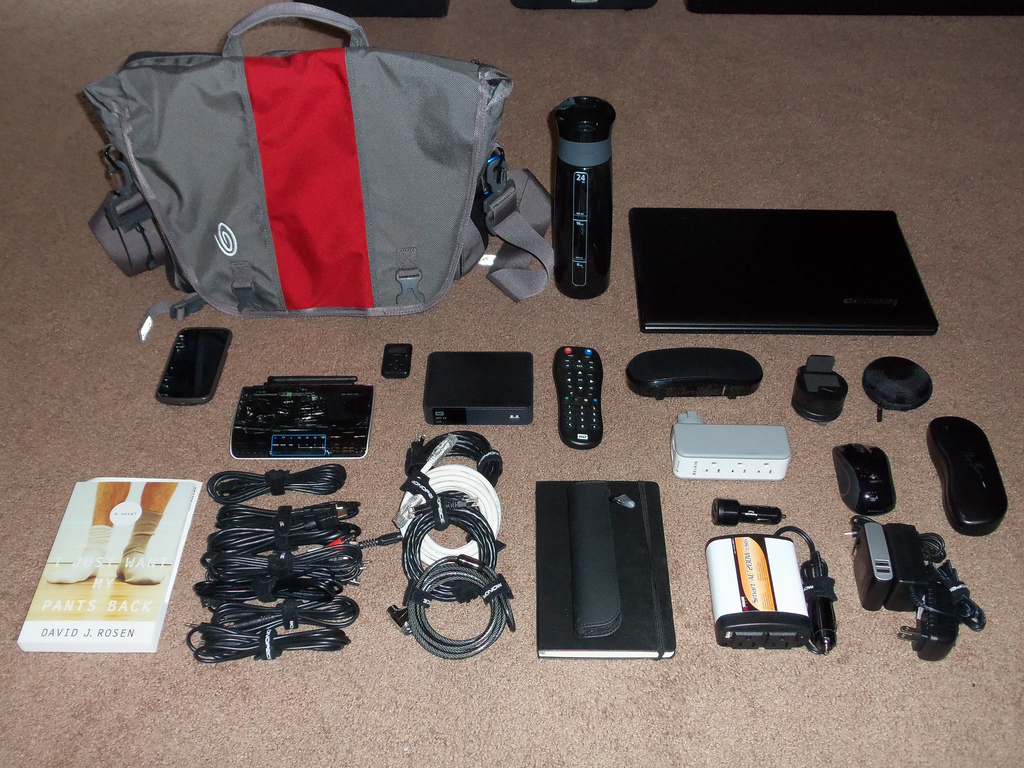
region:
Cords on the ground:
[184, 416, 524, 669]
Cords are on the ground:
[171, 419, 522, 676]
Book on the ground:
[10, 456, 219, 666]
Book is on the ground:
[13, 460, 213, 664]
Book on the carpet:
[11, 460, 214, 670]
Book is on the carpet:
[7, 457, 213, 674]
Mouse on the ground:
[823, 428, 915, 521]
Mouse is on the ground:
[820, 431, 907, 521]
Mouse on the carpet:
[822, 430, 902, 526]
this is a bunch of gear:
[96, 124, 926, 679]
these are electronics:
[64, 101, 909, 636]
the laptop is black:
[593, 177, 1008, 370]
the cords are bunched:
[204, 470, 464, 709]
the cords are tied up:
[190, 458, 397, 703]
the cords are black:
[234, 508, 371, 668]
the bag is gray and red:
[146, 78, 421, 276]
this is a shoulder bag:
[157, 69, 543, 346]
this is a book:
[58, 440, 183, 717]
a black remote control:
[550, 340, 605, 451]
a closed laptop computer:
[623, 200, 941, 336]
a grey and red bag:
[78, 1, 562, 321]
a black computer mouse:
[831, 438, 890, 509]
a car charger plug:
[711, 495, 788, 525]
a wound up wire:
[391, 552, 518, 658]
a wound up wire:
[398, 500, 498, 602]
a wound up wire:
[403, 431, 501, 489]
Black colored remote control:
[550, 335, 611, 452]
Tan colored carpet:
[7, 0, 1017, 766]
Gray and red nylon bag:
[70, 1, 554, 321]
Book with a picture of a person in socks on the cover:
[14, 474, 205, 653]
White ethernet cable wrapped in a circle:
[392, 464, 504, 573]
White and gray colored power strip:
[667, 404, 797, 484]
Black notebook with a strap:
[533, 474, 676, 667]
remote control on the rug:
[548, 328, 610, 458]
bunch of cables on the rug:
[187, 461, 358, 671]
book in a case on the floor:
[525, 459, 671, 665]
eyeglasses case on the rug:
[623, 329, 767, 403]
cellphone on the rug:
[149, 313, 236, 415]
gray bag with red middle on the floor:
[64, 0, 539, 326]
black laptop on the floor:
[631, 180, 932, 339]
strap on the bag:
[84, 177, 161, 282]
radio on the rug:
[231, 372, 372, 467]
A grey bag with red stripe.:
[69, 0, 559, 340]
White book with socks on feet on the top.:
[18, 476, 205, 654]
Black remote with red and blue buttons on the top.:
[552, 346, 603, 452]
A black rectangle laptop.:
[626, 202, 939, 336]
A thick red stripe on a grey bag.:
[245, 47, 378, 313]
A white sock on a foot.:
[47, 524, 114, 585]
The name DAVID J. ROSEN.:
[40, 627, 136, 638]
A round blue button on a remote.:
[583, 344, 596, 357]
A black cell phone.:
[152, 325, 232, 406]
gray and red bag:
[46, 28, 474, 291]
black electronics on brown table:
[143, 314, 226, 403]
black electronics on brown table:
[185, 457, 375, 677]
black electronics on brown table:
[233, 355, 374, 461]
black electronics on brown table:
[625, 178, 952, 349]